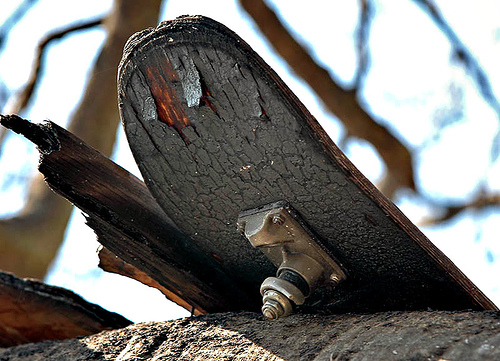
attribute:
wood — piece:
[37, 297, 490, 359]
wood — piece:
[205, 315, 261, 353]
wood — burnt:
[139, 95, 256, 195]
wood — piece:
[0, 308, 497, 360]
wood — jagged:
[3, 114, 243, 314]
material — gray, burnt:
[2, 305, 499, 357]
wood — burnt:
[111, 6, 498, 315]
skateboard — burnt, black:
[112, 16, 498, 328]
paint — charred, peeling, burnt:
[123, 33, 225, 145]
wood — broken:
[8, 111, 89, 209]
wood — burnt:
[50, 150, 250, 317]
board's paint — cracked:
[115, 12, 498, 310]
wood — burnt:
[0, 270, 136, 347]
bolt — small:
[330, 272, 345, 287]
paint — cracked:
[134, 56, 232, 150]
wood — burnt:
[130, 310, 261, 357]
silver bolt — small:
[268, 212, 286, 229]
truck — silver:
[236, 198, 348, 324]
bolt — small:
[234, 222, 244, 234]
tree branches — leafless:
[2, 2, 499, 254]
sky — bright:
[2, 0, 498, 320]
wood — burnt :
[317, 176, 432, 304]